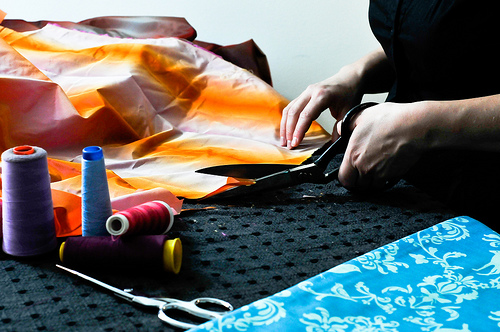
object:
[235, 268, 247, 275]
hole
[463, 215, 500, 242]
edge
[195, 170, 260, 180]
edge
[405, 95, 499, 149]
arm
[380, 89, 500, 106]
edge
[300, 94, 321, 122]
part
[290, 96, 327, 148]
finger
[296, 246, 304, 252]
bad sentence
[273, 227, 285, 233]
bad sentence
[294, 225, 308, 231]
bad sentence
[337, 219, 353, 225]
bad sentence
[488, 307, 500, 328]
pattern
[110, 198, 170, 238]
thread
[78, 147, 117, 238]
blue thread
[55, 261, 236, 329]
scissors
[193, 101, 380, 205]
scissors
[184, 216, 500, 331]
blue cloth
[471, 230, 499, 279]
white design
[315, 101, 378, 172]
black handle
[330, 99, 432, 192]
woman's hand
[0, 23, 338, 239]
material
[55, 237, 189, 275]
spool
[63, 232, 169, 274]
thread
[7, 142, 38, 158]
spool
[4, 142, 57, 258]
thread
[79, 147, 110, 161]
spool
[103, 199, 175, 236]
spool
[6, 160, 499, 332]
work table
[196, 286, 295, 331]
flower designs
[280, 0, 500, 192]
woman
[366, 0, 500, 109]
black blouse